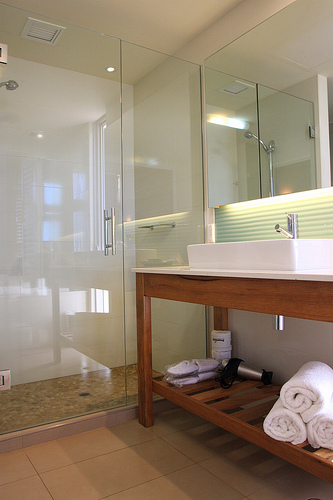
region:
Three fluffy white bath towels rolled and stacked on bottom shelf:
[262, 358, 330, 457]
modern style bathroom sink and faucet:
[177, 205, 331, 269]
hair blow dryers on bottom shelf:
[215, 350, 279, 389]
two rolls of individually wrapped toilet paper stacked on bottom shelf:
[207, 324, 236, 373]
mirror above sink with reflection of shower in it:
[112, 62, 331, 274]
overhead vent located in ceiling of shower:
[3, 12, 84, 56]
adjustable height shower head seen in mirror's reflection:
[238, 119, 278, 192]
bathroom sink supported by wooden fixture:
[121, 209, 331, 461]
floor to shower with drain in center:
[2, 359, 160, 433]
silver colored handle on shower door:
[100, 200, 118, 265]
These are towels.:
[271, 361, 330, 439]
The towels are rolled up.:
[266, 363, 331, 450]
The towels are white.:
[272, 357, 332, 448]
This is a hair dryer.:
[213, 342, 280, 392]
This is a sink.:
[196, 199, 322, 281]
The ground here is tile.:
[30, 439, 220, 497]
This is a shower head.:
[1, 74, 28, 105]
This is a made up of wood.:
[145, 378, 273, 431]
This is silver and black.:
[220, 361, 268, 383]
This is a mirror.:
[189, 85, 330, 202]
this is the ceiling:
[149, 6, 180, 28]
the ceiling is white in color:
[123, 8, 187, 32]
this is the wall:
[204, 33, 226, 45]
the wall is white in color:
[205, 28, 224, 41]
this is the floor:
[54, 448, 131, 487]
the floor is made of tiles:
[61, 436, 147, 490]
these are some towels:
[264, 361, 331, 444]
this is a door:
[20, 24, 127, 399]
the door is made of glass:
[16, 141, 67, 293]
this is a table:
[190, 268, 260, 413]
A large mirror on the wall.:
[203, 1, 330, 242]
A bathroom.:
[0, 2, 328, 498]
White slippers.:
[165, 357, 219, 385]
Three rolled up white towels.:
[264, 360, 332, 451]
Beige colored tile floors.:
[0, 400, 332, 498]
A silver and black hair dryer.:
[219, 355, 273, 388]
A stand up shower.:
[1, 2, 211, 432]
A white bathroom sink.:
[181, 236, 330, 272]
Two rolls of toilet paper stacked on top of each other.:
[211, 331, 230, 359]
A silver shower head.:
[241, 127, 284, 196]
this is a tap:
[271, 210, 300, 236]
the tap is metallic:
[273, 213, 300, 236]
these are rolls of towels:
[273, 371, 327, 445]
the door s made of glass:
[24, 74, 139, 400]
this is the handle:
[99, 203, 118, 251]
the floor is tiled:
[111, 444, 189, 490]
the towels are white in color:
[270, 375, 328, 438]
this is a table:
[183, 280, 216, 303]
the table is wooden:
[205, 391, 247, 419]